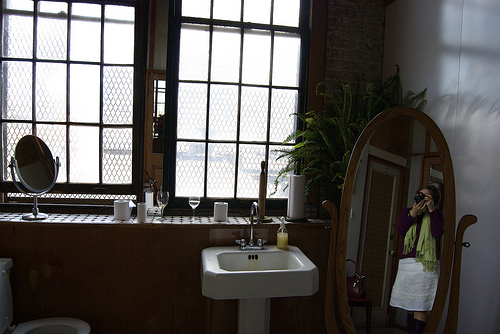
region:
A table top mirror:
[10, 130, 65, 222]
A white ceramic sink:
[197, 240, 328, 298]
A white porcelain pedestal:
[236, 290, 278, 332]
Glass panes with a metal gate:
[100, 63, 136, 182]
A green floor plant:
[302, 106, 341, 183]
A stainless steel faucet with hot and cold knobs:
[234, 198, 274, 254]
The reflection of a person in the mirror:
[385, 173, 447, 311]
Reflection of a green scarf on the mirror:
[393, 215, 443, 271]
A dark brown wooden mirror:
[317, 98, 480, 328]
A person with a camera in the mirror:
[405, 181, 441, 221]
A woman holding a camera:
[390, 183, 450, 324]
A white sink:
[204, 245, 318, 332]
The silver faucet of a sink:
[240, 202, 265, 249]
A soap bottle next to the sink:
[273, 218, 287, 248]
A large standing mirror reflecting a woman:
[346, 115, 453, 332]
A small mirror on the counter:
[10, 135, 62, 220]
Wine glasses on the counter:
[156, 192, 202, 219]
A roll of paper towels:
[284, 171, 309, 222]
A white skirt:
[392, 257, 437, 310]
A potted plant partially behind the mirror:
[282, 80, 425, 224]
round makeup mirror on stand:
[10, 132, 62, 219]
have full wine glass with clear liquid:
[186, 190, 201, 222]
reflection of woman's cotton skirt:
[386, 252, 440, 312]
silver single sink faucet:
[235, 202, 270, 252]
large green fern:
[273, 68, 428, 208]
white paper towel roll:
[285, 172, 306, 219]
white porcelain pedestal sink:
[200, 241, 322, 332]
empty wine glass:
[153, 188, 170, 223]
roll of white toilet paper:
[113, 194, 132, 221]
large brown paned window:
[167, 0, 313, 207]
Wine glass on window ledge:
[154, 190, 171, 222]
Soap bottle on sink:
[269, 216, 290, 249]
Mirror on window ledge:
[6, 134, 62, 221]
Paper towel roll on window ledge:
[284, 156, 306, 223]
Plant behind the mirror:
[292, 67, 439, 222]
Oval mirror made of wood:
[320, 107, 477, 332]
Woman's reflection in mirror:
[390, 177, 442, 330]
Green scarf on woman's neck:
[406, 202, 435, 272]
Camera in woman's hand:
[406, 190, 431, 209]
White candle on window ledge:
[206, 194, 231, 221]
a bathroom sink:
[193, 237, 322, 308]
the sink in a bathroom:
[193, 242, 322, 305]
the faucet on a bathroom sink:
[237, 198, 265, 255]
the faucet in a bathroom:
[228, 198, 270, 251]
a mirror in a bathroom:
[338, 103, 459, 333]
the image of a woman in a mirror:
[360, 149, 443, 323]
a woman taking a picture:
[406, 183, 438, 217]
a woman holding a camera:
[407, 170, 439, 238]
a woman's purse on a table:
[338, 250, 365, 301]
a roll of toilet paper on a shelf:
[82, 198, 132, 223]